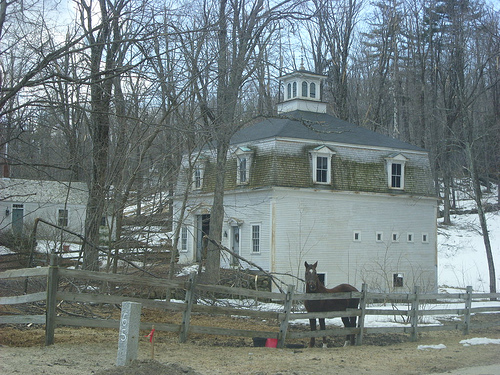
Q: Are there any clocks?
A: No, there are no clocks.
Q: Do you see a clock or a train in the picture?
A: No, there are no clocks or trains.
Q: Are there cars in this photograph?
A: No, there are no cars.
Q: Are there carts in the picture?
A: No, there are no carts.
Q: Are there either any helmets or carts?
A: No, there are no carts or helmets.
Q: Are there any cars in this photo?
A: No, there are no cars.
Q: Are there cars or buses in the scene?
A: No, there are no cars or buses.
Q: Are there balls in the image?
A: No, there are no balls.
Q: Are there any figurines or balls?
A: No, there are no balls or figurines.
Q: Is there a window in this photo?
A: Yes, there is a window.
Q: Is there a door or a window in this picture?
A: Yes, there is a window.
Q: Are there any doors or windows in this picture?
A: Yes, there is a window.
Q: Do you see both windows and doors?
A: Yes, there are both a window and doors.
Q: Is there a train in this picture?
A: No, there are no trains.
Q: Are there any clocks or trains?
A: No, there are no trains or clocks.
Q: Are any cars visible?
A: No, there are no cars.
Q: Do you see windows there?
A: Yes, there is a window.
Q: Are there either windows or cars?
A: Yes, there is a window.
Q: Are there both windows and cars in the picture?
A: No, there is a window but no cars.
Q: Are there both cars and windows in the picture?
A: No, there is a window but no cars.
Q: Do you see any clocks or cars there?
A: No, there are no clocks or cars.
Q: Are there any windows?
A: Yes, there is a window.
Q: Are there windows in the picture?
A: Yes, there is a window.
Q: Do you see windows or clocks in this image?
A: Yes, there is a window.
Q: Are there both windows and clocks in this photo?
A: No, there is a window but no clocks.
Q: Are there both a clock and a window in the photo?
A: No, there is a window but no clocks.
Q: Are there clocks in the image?
A: No, there are no clocks.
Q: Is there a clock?
A: No, there are no clocks.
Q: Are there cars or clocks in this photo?
A: No, there are no clocks or cars.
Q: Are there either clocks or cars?
A: No, there are no clocks or cars.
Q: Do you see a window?
A: Yes, there is a window.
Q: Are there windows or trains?
A: Yes, there is a window.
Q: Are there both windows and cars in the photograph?
A: No, there is a window but no cars.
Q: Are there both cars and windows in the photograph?
A: No, there is a window but no cars.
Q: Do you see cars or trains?
A: No, there are no cars or trains.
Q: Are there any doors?
A: Yes, there is a door.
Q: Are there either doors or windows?
A: Yes, there is a door.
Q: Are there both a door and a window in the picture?
A: Yes, there are both a door and a window.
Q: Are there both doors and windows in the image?
A: Yes, there are both a door and windows.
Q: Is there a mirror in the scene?
A: No, there are no mirrors.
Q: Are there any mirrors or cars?
A: No, there are no mirrors or cars.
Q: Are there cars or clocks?
A: No, there are no cars or clocks.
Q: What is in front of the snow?
A: The building is in front of the snow.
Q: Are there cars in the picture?
A: No, there are no cars.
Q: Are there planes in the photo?
A: No, there are no planes.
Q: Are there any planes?
A: No, there are no planes.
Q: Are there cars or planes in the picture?
A: No, there are no planes or cars.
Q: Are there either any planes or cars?
A: No, there are no planes or cars.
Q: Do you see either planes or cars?
A: No, there are no planes or cars.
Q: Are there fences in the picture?
A: Yes, there is a fence.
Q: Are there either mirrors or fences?
A: Yes, there is a fence.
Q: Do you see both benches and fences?
A: No, there is a fence but no benches.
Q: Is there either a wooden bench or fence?
A: Yes, there is a wood fence.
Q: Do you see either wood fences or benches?
A: Yes, there is a wood fence.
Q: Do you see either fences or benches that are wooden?
A: Yes, the fence is wooden.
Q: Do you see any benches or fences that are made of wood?
A: Yes, the fence is made of wood.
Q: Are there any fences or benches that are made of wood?
A: Yes, the fence is made of wood.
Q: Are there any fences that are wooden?
A: Yes, there is a wood fence.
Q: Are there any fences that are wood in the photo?
A: Yes, there is a wood fence.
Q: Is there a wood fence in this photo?
A: Yes, there is a wood fence.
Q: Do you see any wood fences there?
A: Yes, there is a wood fence.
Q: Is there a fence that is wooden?
A: Yes, there is a fence that is wooden.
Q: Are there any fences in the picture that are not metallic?
A: Yes, there is a wooden fence.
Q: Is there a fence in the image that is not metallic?
A: Yes, there is a wooden fence.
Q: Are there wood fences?
A: Yes, there is a fence that is made of wood.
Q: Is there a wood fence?
A: Yes, there is a fence that is made of wood.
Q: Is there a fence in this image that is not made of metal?
A: Yes, there is a fence that is made of wood.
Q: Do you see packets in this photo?
A: No, there are no packets.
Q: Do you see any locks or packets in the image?
A: No, there are no packets or locks.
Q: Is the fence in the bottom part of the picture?
A: Yes, the fence is in the bottom of the image.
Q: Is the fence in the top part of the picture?
A: No, the fence is in the bottom of the image.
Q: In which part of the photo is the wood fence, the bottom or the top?
A: The fence is in the bottom of the image.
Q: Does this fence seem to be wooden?
A: Yes, the fence is wooden.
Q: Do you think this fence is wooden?
A: Yes, the fence is wooden.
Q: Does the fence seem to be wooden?
A: Yes, the fence is wooden.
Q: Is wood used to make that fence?
A: Yes, the fence is made of wood.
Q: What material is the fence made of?
A: The fence is made of wood.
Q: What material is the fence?
A: The fence is made of wood.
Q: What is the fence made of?
A: The fence is made of wood.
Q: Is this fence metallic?
A: No, the fence is wooden.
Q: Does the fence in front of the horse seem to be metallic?
A: No, the fence is wooden.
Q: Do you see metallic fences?
A: No, there is a fence but it is wooden.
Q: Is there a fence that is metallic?
A: No, there is a fence but it is wooden.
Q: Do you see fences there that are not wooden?
A: No, there is a fence but it is wooden.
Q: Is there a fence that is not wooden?
A: No, there is a fence but it is wooden.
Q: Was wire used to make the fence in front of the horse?
A: No, the fence is made of wood.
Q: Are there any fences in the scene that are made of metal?
A: No, there is a fence but it is made of wood.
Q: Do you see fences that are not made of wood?
A: No, there is a fence but it is made of wood.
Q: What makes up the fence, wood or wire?
A: The fence is made of wood.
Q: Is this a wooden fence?
A: Yes, this is a wooden fence.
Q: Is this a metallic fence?
A: No, this is a wooden fence.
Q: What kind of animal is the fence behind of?
A: The fence is behind the horse.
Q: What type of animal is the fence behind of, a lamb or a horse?
A: The fence is behind a horse.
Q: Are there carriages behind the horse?
A: No, there is a fence behind the horse.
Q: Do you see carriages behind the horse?
A: No, there is a fence behind the horse.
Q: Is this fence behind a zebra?
A: No, the fence is behind the horse.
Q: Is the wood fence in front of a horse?
A: No, the fence is behind a horse.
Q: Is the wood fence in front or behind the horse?
A: The fence is behind the horse.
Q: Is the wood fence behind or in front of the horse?
A: The fence is behind the horse.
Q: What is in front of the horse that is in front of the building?
A: The fence is in front of the horse.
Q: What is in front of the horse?
A: The fence is in front of the horse.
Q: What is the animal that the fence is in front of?
A: The animal is a horse.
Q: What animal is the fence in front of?
A: The fence is in front of the horse.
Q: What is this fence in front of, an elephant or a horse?
A: The fence is in front of a horse.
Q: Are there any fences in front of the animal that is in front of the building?
A: Yes, there is a fence in front of the horse.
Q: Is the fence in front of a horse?
A: Yes, the fence is in front of a horse.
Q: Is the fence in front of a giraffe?
A: No, the fence is in front of a horse.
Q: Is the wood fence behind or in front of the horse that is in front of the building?
A: The fence is in front of the horse.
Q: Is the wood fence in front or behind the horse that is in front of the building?
A: The fence is in front of the horse.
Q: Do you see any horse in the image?
A: Yes, there is a horse.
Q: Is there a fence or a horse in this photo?
A: Yes, there is a horse.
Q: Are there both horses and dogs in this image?
A: No, there is a horse but no dogs.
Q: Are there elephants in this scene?
A: No, there are no elephants.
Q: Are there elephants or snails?
A: No, there are no elephants or snails.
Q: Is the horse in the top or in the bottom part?
A: The horse is in the bottom of the image.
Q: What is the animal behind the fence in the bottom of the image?
A: The animal is a horse.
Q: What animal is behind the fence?
A: The animal is a horse.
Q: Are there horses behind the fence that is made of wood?
A: Yes, there is a horse behind the fence.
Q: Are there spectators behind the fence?
A: No, there is a horse behind the fence.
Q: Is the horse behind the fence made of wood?
A: Yes, the horse is behind the fence.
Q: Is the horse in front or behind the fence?
A: The horse is behind the fence.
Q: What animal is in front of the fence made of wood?
A: The horse is in front of the fence.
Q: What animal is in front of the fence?
A: The horse is in front of the fence.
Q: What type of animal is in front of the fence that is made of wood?
A: The animal is a horse.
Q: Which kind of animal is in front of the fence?
A: The animal is a horse.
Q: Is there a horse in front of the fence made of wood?
A: Yes, there is a horse in front of the fence.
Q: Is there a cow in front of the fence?
A: No, there is a horse in front of the fence.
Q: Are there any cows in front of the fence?
A: No, there is a horse in front of the fence.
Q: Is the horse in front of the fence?
A: Yes, the horse is in front of the fence.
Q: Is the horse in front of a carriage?
A: No, the horse is in front of the fence.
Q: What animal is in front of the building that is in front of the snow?
A: The horse is in front of the building.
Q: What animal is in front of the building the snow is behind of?
A: The animal is a horse.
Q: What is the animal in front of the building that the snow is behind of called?
A: The animal is a horse.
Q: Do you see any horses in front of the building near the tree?
A: Yes, there is a horse in front of the building.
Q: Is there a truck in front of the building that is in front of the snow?
A: No, there is a horse in front of the building.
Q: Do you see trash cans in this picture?
A: No, there are no trash cans.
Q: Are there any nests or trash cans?
A: No, there are no trash cans or nests.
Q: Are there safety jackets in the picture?
A: No, there are no safety jackets.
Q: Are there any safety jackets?
A: No, there are no safety jackets.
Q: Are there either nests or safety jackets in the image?
A: No, there are no safety jackets or nests.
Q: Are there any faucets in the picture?
A: No, there are no faucets.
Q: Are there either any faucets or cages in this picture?
A: No, there are no faucets or cages.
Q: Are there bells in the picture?
A: No, there are no bells.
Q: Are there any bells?
A: No, there are no bells.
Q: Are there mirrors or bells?
A: No, there are no bells or mirrors.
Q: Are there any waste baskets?
A: No, there are no waste baskets.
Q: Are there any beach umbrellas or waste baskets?
A: No, there are no waste baskets or beach umbrellas.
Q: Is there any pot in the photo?
A: No, there are no pots.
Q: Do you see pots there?
A: No, there are no pots.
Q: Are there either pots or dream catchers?
A: No, there are no pots or dream catchers.